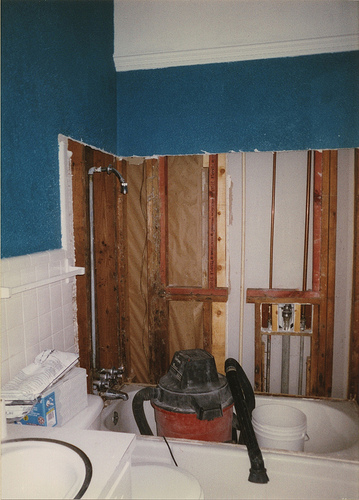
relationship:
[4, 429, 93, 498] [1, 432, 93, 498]
trim on edge of sink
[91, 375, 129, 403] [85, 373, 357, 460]
faucet in bathtub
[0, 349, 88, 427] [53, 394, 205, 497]
package on toilet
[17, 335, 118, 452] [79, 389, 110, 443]
items on top of tank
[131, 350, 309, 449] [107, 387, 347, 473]
items inside bathtub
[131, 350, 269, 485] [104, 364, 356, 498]
items inside bathtub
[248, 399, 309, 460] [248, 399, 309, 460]
bucket in bucket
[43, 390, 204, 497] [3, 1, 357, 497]
toilet in room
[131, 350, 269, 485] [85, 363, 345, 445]
items in tub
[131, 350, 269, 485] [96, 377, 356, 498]
items in bathtub